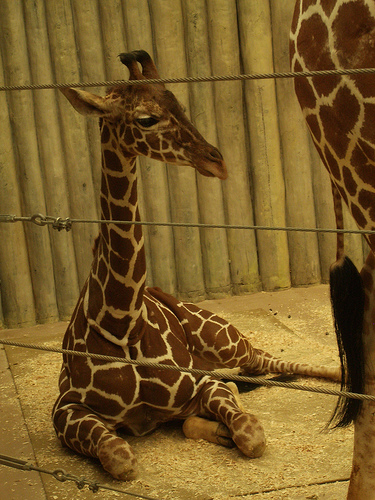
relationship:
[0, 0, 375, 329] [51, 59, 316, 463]
fence behind giraffe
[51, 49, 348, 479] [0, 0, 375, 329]
giraffe near fence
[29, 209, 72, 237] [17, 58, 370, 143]
hook on fence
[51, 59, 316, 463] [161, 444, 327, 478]
giraffe lying on sawdust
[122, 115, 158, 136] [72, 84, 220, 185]
eye on head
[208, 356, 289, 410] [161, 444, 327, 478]
tail on sawdust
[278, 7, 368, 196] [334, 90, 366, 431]
giraffe has tail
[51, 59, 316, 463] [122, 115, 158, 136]
giraffe has eye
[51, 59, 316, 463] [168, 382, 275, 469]
giraffe has leg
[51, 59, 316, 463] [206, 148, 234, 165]
giraffe has nostril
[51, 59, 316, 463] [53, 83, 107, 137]
giraffe has ear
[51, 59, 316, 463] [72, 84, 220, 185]
giraffe has head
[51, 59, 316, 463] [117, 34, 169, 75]
giraffe has ossicles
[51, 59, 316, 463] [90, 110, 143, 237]
giraffe has neck